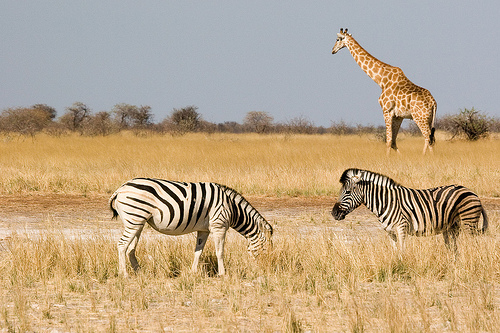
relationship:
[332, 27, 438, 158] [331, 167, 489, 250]
giraffe behind zebra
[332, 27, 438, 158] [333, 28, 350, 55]
giraffe has head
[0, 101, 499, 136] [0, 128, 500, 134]
tree line along horizon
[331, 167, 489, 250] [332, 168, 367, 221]
zebra has head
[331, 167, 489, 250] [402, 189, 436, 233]
zebra has stripes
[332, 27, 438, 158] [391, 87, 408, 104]
giraffe has spots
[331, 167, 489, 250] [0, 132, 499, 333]
zebra on plain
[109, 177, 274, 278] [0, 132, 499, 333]
zebras on plain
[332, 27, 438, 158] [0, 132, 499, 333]
giraffe on plain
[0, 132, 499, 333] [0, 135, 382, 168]
plain has grass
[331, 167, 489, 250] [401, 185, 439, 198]
zebra has back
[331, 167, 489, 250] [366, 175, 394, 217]
zebra has neck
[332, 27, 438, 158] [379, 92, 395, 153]
giraffe has leg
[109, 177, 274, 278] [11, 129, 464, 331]
zebras in field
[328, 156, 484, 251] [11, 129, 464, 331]
zebra in field